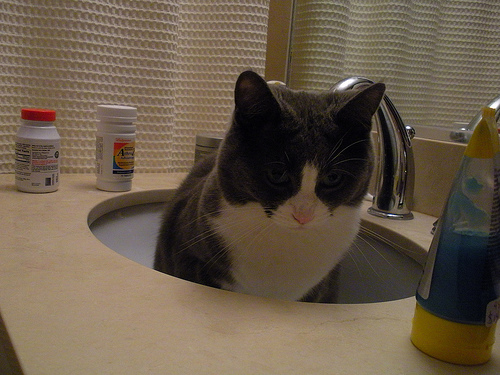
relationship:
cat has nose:
[155, 68, 389, 301] [290, 199, 318, 228]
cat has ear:
[155, 68, 389, 301] [231, 67, 289, 135]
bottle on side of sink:
[93, 101, 137, 194] [87, 189, 428, 305]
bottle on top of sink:
[93, 101, 137, 194] [87, 189, 428, 305]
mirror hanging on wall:
[282, 3, 499, 146] [265, 1, 466, 219]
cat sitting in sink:
[155, 68, 389, 301] [87, 189, 428, 305]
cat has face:
[155, 68, 389, 301] [218, 131, 375, 233]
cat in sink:
[155, 68, 389, 301] [87, 189, 428, 305]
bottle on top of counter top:
[93, 101, 137, 194] [2, 177, 499, 373]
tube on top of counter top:
[414, 95, 499, 330] [2, 177, 499, 373]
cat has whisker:
[155, 68, 389, 301] [173, 205, 292, 231]